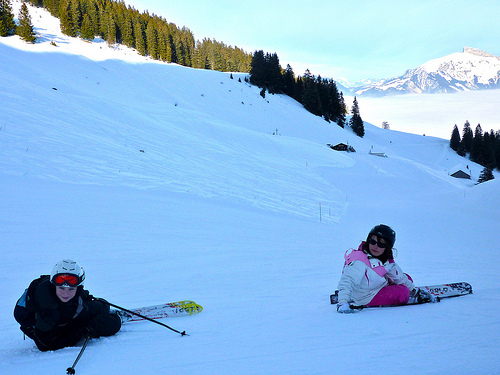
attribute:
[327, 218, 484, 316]
girl — skiing, seated, turned around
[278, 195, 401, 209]
ground — snow covered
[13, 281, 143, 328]
boy — sitting on ground, skiing, on skis, wearing black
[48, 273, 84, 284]
red googles — black too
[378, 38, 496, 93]
mountain — snow covered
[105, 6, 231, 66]
trees — abundant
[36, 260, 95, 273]
white helmet — for skiing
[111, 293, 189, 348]
ski poles — side, doubled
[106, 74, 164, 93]
snow — white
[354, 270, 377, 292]
jacket — pink, white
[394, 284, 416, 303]
knees — bent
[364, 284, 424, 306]
pants — pink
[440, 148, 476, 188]
house — snow covered